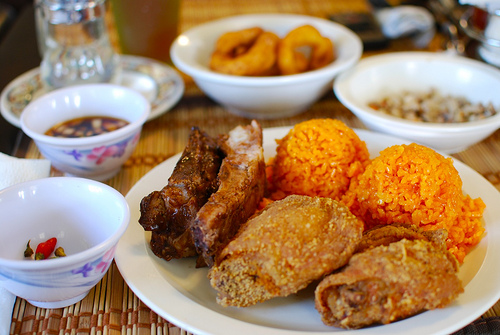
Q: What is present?
A: Food.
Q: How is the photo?
A: Clear.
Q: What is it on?
A: Plate.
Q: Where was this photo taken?
A: Close-up table view.